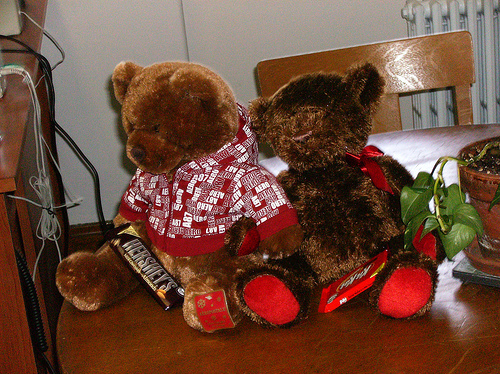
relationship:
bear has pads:
[241, 63, 435, 321] [241, 274, 304, 326]